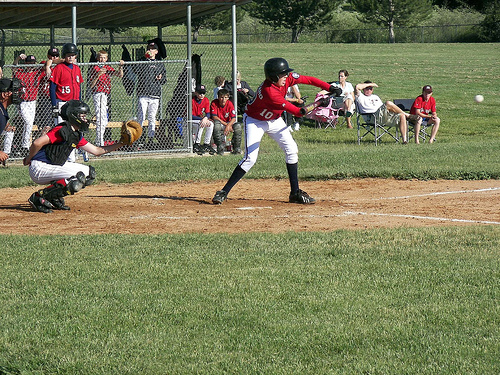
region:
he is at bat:
[186, 33, 370, 238]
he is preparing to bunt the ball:
[202, 37, 379, 215]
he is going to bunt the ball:
[197, 26, 385, 222]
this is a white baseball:
[457, 76, 496, 119]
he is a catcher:
[17, 85, 172, 228]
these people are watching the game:
[346, 66, 476, 147]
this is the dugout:
[5, 32, 244, 145]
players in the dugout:
[8, 35, 243, 150]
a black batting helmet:
[261, 52, 304, 89]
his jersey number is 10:
[233, 38, 341, 128]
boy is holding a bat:
[204, 49, 343, 211]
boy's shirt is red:
[248, 74, 333, 125]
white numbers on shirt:
[258, 105, 276, 120]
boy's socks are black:
[218, 159, 300, 199]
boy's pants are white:
[229, 105, 301, 172]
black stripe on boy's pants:
[232, 111, 259, 167]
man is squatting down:
[18, 92, 143, 214]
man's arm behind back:
[18, 130, 50, 165]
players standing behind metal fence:
[1, 29, 198, 159]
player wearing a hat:
[264, 52, 301, 90]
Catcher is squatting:
[21, 84, 115, 221]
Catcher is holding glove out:
[71, 104, 155, 167]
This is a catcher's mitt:
[116, 115, 153, 152]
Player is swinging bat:
[285, 63, 357, 143]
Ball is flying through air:
[451, 74, 491, 117]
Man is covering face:
[357, 73, 387, 105]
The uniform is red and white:
[217, 60, 326, 183]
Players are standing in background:
[6, 40, 143, 141]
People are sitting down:
[343, 77, 450, 158]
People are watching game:
[360, 65, 442, 141]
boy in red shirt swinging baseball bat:
[211, 56, 347, 226]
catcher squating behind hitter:
[20, 97, 147, 220]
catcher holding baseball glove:
[17, 94, 144, 226]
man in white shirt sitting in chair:
[352, 77, 421, 146]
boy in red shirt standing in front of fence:
[48, 43, 86, 129]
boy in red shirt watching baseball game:
[210, 87, 245, 152]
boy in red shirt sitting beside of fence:
[186, 82, 220, 157]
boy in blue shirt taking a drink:
[128, 39, 168, 151]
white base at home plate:
[236, 199, 273, 216]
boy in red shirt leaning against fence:
[9, 50, 53, 160]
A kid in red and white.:
[211, 55, 341, 206]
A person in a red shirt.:
[410, 82, 441, 144]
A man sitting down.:
[353, 78, 420, 150]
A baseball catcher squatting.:
[21, 99, 143, 215]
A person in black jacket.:
[131, 40, 168, 148]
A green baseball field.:
[0, 223, 499, 373]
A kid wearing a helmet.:
[51, 41, 86, 123]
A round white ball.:
[472, 93, 487, 103]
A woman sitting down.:
[331, 68, 357, 128]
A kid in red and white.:
[87, 49, 124, 146]